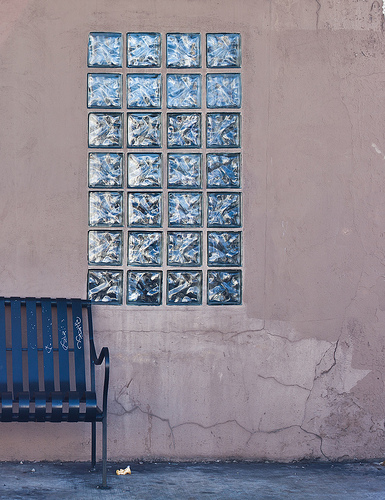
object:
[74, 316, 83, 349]
marking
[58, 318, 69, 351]
marking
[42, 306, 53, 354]
marking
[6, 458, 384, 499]
ground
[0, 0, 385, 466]
wall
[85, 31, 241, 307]
window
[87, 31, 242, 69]
row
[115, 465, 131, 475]
piece litter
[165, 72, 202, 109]
square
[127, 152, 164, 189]
square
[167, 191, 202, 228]
square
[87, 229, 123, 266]
square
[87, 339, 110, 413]
armrest railing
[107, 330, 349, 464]
crack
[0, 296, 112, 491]
bench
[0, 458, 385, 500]
sidewalk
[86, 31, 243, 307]
decorations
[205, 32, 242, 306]
seven square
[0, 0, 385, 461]
building